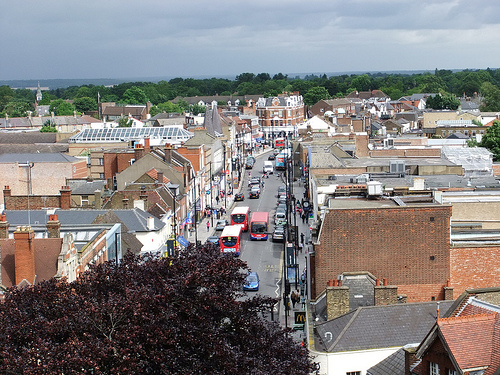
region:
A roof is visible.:
[411, 302, 475, 358]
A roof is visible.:
[407, 326, 439, 373]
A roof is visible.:
[396, 341, 436, 373]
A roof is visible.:
[378, 313, 442, 373]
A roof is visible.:
[438, 305, 491, 371]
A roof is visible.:
[436, 303, 493, 334]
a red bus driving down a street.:
[238, 203, 270, 247]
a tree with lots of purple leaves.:
[0, 242, 320, 374]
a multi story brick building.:
[306, 188, 461, 314]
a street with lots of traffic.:
[197, 128, 307, 345]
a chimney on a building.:
[11, 211, 47, 298]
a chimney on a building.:
[0, 77, 496, 112]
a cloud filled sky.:
[0, 1, 497, 83]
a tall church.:
[27, 81, 64, 131]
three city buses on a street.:
[213, 183, 288, 267]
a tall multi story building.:
[253, 88, 327, 143]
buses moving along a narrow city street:
[220, 135, 292, 282]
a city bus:
[218, 222, 243, 255]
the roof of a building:
[317, 205, 453, 287]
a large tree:
[1, 244, 313, 373]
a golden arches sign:
[294, 308, 306, 325]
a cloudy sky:
[2, 4, 497, 68]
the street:
[254, 245, 275, 271]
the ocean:
[6, 80, 117, 87]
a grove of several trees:
[106, 73, 496, 90]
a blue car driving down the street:
[241, 273, 259, 289]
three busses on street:
[215, 198, 277, 268]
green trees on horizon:
[209, 72, 356, 91]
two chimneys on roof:
[322, 275, 405, 318]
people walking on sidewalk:
[274, 276, 304, 316]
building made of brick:
[455, 254, 495, 286]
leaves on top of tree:
[114, 256, 211, 331]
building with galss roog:
[79, 123, 186, 142]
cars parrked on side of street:
[272, 186, 288, 251]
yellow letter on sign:
[289, 307, 309, 332]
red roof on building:
[439, 323, 487, 365]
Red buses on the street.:
[216, 123, 291, 255]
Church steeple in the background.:
[32, 79, 48, 109]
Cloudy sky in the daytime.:
[0, 1, 496, 88]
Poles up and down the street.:
[116, 135, 312, 330]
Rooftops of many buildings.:
[8, 90, 495, 372]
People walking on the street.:
[178, 124, 313, 324]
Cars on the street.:
[188, 125, 303, 317]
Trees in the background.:
[6, 69, 493, 164]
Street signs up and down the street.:
[176, 131, 317, 321]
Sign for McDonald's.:
[291, 311, 311, 325]